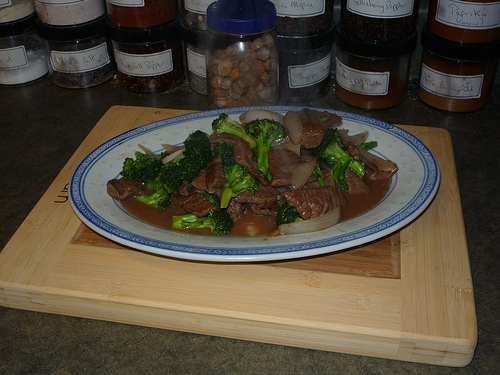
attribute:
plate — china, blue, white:
[80, 96, 450, 269]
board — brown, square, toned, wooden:
[9, 87, 493, 369]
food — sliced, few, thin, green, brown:
[139, 132, 376, 216]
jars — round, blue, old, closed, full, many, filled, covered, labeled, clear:
[0, 1, 499, 115]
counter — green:
[1, 84, 500, 370]